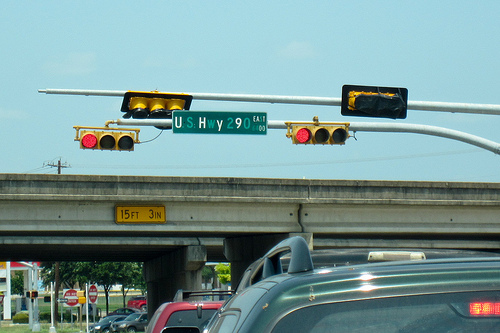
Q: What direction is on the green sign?
A: East.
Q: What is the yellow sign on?
A: An overpass.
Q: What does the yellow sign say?
A: 15ft 3 in.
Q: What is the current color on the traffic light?
A: Red.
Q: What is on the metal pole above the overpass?
A: Traffic lights.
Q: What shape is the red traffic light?
A: Circle.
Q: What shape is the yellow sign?
A: Rectangle.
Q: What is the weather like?
A: Sunny.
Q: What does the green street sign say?
A: U.S. Hwy 290 EAST 6400.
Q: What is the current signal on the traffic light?
A: Red.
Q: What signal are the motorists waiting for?
A: Green.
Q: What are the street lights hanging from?
A: Pole.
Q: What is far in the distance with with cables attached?
A: Telephone pole.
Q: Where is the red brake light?
A: Closest car.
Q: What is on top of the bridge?
A: Road.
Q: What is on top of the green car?
A: Roof rack.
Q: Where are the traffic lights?
A: Above road.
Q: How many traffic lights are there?
A: Four.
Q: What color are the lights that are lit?
A: Red.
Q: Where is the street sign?
A: Between the traffic lights.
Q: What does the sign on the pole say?
A: U.S. Hwy 290.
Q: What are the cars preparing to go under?
A: A bridge.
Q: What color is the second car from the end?
A: Red.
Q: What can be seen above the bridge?
A: A power pole.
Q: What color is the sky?
A: Blue.